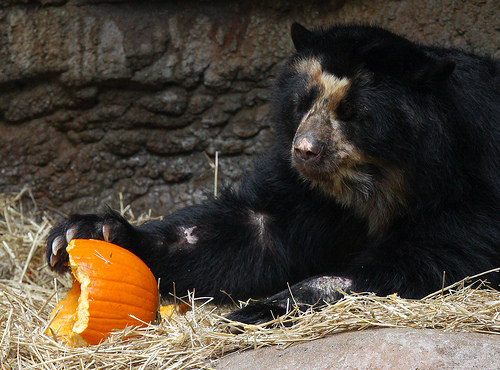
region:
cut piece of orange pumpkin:
[49, 233, 176, 337]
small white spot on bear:
[178, 220, 208, 244]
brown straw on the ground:
[156, 322, 222, 349]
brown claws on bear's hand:
[43, 226, 110, 249]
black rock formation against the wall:
[38, 38, 213, 161]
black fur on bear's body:
[338, 230, 445, 262]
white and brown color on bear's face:
[265, 53, 390, 184]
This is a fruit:
[35, 238, 170, 355]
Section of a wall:
[34, 121, 100, 173]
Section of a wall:
[92, 105, 187, 169]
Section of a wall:
[22, 25, 151, 115]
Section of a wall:
[142, 24, 269, 129]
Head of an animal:
[260, 18, 485, 230]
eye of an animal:
[323, 86, 380, 139]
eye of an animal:
[282, 77, 331, 121]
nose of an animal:
[282, 127, 320, 162]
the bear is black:
[78, 28, 465, 306]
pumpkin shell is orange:
[37, 198, 166, 363]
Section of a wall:
[23, 113, 132, 206]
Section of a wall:
[104, 128, 234, 201]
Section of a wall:
[21, 30, 201, 171]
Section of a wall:
[191, 22, 281, 157]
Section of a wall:
[25, 97, 232, 212]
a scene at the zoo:
[5, 17, 496, 367]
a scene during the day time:
[6, 13, 497, 350]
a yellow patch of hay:
[7, 173, 484, 369]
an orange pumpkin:
[25, 193, 155, 364]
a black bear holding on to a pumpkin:
[46, 21, 496, 362]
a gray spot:
[190, 303, 472, 366]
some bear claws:
[20, 189, 165, 302]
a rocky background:
[7, 39, 269, 220]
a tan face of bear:
[254, 31, 494, 246]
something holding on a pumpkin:
[27, 18, 497, 329]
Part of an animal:
[25, 194, 169, 261]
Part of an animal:
[153, 201, 244, 301]